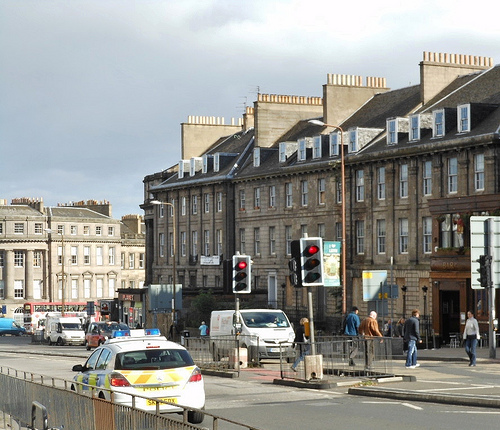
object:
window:
[295, 173, 315, 212]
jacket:
[359, 317, 381, 336]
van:
[207, 305, 298, 367]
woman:
[450, 312, 489, 364]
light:
[135, 2, 500, 55]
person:
[408, 308, 424, 368]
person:
[463, 310, 480, 371]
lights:
[108, 318, 161, 336]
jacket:
[343, 313, 359, 334]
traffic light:
[302, 238, 321, 257]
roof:
[1, 204, 112, 221]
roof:
[152, 59, 499, 181]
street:
[2, 352, 498, 428]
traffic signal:
[302, 239, 331, 284]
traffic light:
[226, 246, 254, 298]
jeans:
[402, 339, 418, 371]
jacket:
[401, 316, 423, 340]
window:
[186, 197, 223, 213]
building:
[0, 63, 498, 355]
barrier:
[0, 366, 251, 428]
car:
[61, 330, 205, 425]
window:
[315, 180, 327, 209]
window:
[253, 187, 261, 209]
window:
[267, 185, 276, 207]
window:
[283, 182, 293, 205]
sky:
[5, 3, 497, 223]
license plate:
[145, 395, 184, 406]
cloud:
[1, 3, 500, 196]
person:
[355, 298, 388, 370]